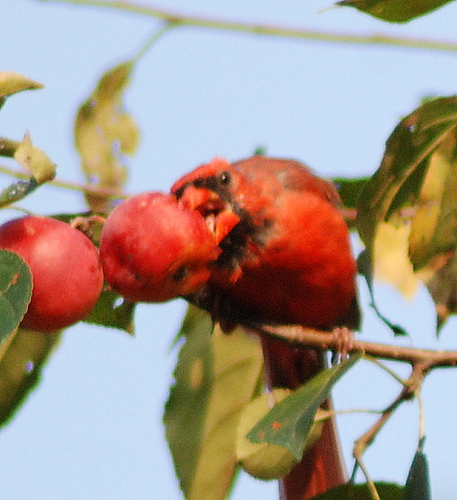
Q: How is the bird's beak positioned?
A: Open.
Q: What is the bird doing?
A: Eating fruit.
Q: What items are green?
A: Leaves.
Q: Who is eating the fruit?
A: The bird.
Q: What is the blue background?
A: Sky.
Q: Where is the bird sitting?
A: On a branch.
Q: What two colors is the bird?
A: Red and black.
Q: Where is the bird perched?
A: In a tree.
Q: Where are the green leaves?
A: On the tree branches.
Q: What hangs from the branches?
A: The red fruit.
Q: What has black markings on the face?
A: The bird.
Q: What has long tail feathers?
A: The bird.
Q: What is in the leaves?
A: Holes.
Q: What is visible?
A: The bird.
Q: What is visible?
A: The bird.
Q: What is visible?
A: The bird.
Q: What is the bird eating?
A: Fruit.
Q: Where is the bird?
A: On the branch.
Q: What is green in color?
A: Leaves.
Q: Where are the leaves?
A: On the tree.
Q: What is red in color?
A: The bird.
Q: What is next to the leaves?
A: A bird is visible.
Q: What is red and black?
A: A bird is visible.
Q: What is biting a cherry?
A: A bird is visible.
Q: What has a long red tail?
A: A bird is visible.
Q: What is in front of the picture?
A: A bird is visible.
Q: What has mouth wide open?
A: A bird is visible.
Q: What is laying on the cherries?
A: The leaves are visible.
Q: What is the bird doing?
A: Eating.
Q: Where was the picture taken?
A: In the trees.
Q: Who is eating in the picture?
A: A bird.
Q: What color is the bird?
A: Red.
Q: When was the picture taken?
A: During the day.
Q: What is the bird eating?
A: An apple.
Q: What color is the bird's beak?
A: Red.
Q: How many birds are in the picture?
A: One.